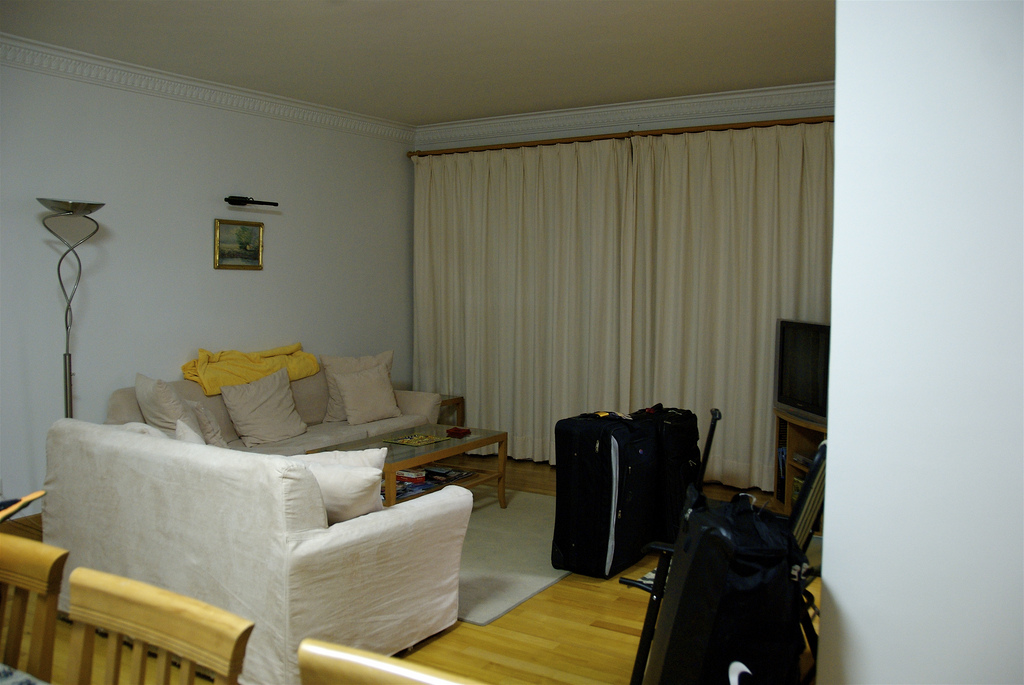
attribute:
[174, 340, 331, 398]
blanket — yellow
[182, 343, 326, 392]
blanket — yellow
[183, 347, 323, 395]
blanket — yellow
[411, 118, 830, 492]
shades — yellow, closed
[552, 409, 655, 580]
bag — black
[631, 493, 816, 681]
luggage — black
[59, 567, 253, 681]
chair — wood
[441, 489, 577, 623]
rug — white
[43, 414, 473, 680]
loveseat — white 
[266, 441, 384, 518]
pillow — white 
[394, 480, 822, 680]
floor — wood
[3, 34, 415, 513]
wall — white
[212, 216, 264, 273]
picture — framed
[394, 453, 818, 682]
floor — wood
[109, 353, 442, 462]
couch — white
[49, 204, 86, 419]
pole — long